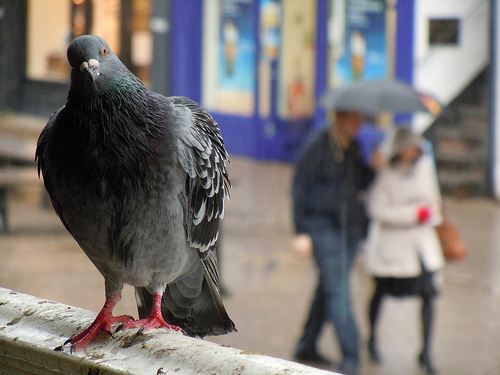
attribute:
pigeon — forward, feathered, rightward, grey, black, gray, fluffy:
[40, 36, 236, 351]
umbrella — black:
[324, 79, 436, 120]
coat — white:
[363, 158, 449, 274]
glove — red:
[417, 206, 427, 221]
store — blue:
[2, 2, 496, 161]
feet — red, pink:
[66, 289, 178, 351]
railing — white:
[0, 282, 328, 374]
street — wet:
[4, 103, 500, 375]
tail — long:
[132, 256, 239, 338]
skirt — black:
[369, 271, 443, 296]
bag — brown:
[436, 219, 462, 259]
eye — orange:
[97, 43, 111, 55]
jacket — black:
[290, 126, 372, 240]